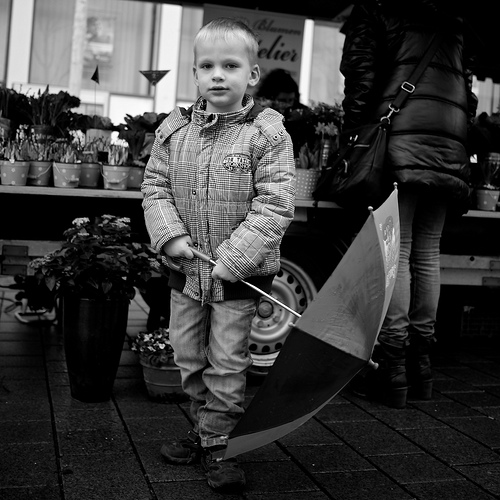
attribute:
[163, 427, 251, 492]
shoes — dark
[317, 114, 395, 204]
handbag — black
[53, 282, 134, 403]
vase — large, black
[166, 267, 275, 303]
trim — black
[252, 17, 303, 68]
words — black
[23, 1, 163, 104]
window — large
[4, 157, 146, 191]
pots — small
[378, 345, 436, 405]
boots — black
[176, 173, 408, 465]
umbrella — multi colored, black, white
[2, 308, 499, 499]
ground — wet, patterned